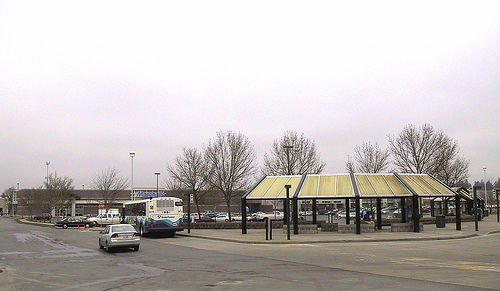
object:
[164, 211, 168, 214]
logo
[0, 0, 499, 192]
sky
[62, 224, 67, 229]
tire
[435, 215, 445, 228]
garbage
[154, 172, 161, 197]
light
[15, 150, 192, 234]
poles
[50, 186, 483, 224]
parking lot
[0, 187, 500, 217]
building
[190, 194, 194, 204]
sign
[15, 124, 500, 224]
trees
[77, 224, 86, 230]
orange cones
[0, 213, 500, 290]
street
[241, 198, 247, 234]
pole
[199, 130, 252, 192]
leaves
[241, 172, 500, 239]
bus stop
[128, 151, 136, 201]
light post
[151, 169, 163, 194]
light post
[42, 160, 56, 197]
light post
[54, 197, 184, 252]
cars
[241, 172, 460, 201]
stand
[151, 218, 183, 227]
lights